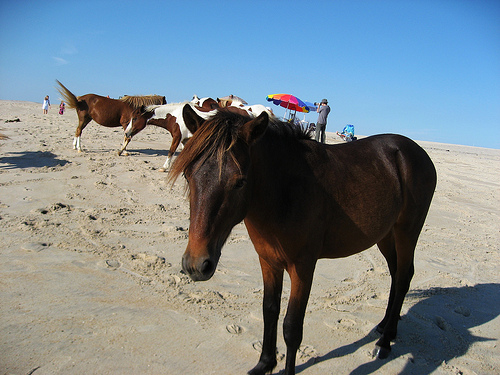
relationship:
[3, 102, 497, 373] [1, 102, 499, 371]
ground has sand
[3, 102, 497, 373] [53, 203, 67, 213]
ground has track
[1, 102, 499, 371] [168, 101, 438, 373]
sand under horse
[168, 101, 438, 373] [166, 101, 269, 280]
horse has head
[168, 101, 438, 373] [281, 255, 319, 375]
horse has leg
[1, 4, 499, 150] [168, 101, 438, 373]
sky above horse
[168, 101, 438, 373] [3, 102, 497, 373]
horse on top of ground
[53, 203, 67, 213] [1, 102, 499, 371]
track on top of sand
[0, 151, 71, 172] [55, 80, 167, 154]
shadow beside horse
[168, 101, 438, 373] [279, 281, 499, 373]
horse has shadow